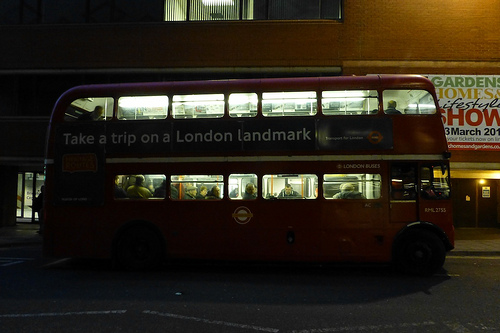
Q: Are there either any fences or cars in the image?
A: No, there are no cars or fences.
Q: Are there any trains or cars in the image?
A: No, there are no cars or trains.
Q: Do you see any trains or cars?
A: No, there are no cars or trains.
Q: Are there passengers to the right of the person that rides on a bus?
A: Yes, there is a passenger to the right of the person.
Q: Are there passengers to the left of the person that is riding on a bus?
A: No, the passenger is to the right of the person.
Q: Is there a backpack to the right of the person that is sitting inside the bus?
A: No, there is a passenger to the right of the person.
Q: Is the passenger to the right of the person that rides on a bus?
A: Yes, the passenger is to the right of the person.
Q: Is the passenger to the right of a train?
A: No, the passenger is to the right of the person.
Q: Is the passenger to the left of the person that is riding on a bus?
A: No, the passenger is to the right of the person.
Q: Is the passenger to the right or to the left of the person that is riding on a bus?
A: The passenger is to the right of the person.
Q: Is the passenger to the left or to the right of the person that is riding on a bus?
A: The passenger is to the right of the person.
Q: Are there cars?
A: No, there are no cars.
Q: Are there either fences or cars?
A: No, there are no cars or fences.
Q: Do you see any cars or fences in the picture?
A: No, there are no cars or fences.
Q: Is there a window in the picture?
A: Yes, there is a window.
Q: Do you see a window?
A: Yes, there is a window.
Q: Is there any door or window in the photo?
A: Yes, there is a window.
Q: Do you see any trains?
A: No, there are no trains.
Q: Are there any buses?
A: Yes, there is a bus.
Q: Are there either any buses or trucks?
A: Yes, there is a bus.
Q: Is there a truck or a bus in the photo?
A: Yes, there is a bus.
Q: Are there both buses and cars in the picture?
A: No, there is a bus but no cars.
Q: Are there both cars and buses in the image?
A: No, there is a bus but no cars.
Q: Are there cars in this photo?
A: No, there are no cars.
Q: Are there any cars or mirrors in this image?
A: No, there are no cars or mirrors.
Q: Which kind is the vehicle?
A: The vehicle is a bus.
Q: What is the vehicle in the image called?
A: The vehicle is a bus.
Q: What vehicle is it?
A: The vehicle is a bus.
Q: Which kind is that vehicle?
A: This is a bus.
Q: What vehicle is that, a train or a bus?
A: This is a bus.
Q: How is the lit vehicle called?
A: The vehicle is a bus.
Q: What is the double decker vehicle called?
A: The vehicle is a bus.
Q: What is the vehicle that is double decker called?
A: The vehicle is a bus.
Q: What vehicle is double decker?
A: The vehicle is a bus.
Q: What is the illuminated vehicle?
A: The vehicle is a bus.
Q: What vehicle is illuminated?
A: The vehicle is a bus.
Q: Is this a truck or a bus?
A: This is a bus.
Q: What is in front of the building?
A: The bus is in front of the building.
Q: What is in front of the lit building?
A: The bus is in front of the building.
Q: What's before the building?
A: The bus is in front of the building.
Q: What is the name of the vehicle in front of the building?
A: The vehicle is a bus.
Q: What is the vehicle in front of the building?
A: The vehicle is a bus.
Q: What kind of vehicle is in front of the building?
A: The vehicle is a bus.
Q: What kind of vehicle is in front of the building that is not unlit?
A: The vehicle is a bus.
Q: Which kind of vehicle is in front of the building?
A: The vehicle is a bus.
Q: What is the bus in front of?
A: The bus is in front of the building.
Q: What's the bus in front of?
A: The bus is in front of the building.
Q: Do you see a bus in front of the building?
A: Yes, there is a bus in front of the building.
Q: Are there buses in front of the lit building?
A: Yes, there is a bus in front of the building.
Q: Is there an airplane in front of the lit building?
A: No, there is a bus in front of the building.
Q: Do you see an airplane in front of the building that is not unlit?
A: No, there is a bus in front of the building.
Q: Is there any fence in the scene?
A: No, there are no fences.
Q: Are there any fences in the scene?
A: No, there are no fences.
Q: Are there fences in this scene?
A: No, there are no fences.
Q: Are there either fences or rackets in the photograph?
A: No, there are no fences or rackets.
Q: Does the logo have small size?
A: Yes, the logo is small.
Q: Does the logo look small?
A: Yes, the logo is small.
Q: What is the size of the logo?
A: The logo is small.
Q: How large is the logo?
A: The logo is small.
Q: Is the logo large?
A: No, the logo is small.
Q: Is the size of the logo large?
A: No, the logo is small.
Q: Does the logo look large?
A: No, the logo is small.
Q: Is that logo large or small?
A: The logo is small.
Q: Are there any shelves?
A: No, there are no shelves.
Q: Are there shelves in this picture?
A: No, there are no shelves.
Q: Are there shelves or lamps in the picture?
A: No, there are no shelves or lamps.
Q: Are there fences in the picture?
A: No, there are no fences.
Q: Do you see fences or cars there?
A: No, there are no fences or cars.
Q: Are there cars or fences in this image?
A: No, there are no fences or cars.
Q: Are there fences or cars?
A: No, there are no fences or cars.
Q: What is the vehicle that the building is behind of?
A: The vehicle is a bus.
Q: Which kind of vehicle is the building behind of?
A: The building is behind the bus.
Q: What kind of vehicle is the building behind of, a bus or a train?
A: The building is behind a bus.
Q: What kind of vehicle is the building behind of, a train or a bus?
A: The building is behind a bus.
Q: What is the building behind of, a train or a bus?
A: The building is behind a bus.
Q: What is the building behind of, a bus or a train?
A: The building is behind a bus.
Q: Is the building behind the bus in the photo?
A: Yes, the building is behind the bus.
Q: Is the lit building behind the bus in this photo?
A: Yes, the building is behind the bus.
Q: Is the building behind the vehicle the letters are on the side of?
A: Yes, the building is behind the bus.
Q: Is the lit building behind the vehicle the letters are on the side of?
A: Yes, the building is behind the bus.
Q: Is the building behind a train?
A: No, the building is behind the bus.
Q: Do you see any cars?
A: No, there are no cars.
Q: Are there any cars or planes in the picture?
A: No, there are no cars or planes.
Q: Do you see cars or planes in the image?
A: No, there are no cars or planes.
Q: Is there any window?
A: Yes, there is a window.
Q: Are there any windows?
A: Yes, there is a window.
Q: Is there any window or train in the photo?
A: Yes, there is a window.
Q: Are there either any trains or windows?
A: Yes, there is a window.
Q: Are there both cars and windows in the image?
A: No, there is a window but no cars.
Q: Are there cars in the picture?
A: No, there are no cars.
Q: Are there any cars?
A: No, there are no cars.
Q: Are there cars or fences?
A: No, there are no cars or fences.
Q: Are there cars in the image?
A: No, there are no cars.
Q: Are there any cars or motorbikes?
A: No, there are no cars or motorbikes.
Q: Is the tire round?
A: Yes, the tire is round.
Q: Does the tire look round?
A: Yes, the tire is round.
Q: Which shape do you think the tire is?
A: The tire is round.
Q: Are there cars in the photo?
A: No, there are no cars.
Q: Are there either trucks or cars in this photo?
A: No, there are no cars or trucks.